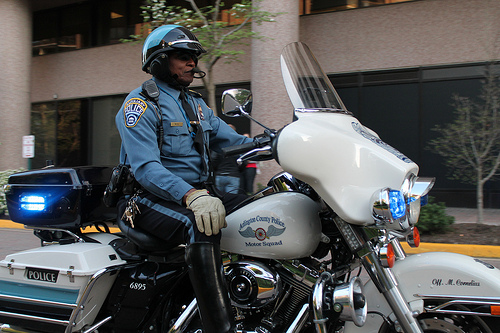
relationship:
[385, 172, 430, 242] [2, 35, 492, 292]
headlight of motorcycle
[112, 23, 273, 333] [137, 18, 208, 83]
cop wearing helmet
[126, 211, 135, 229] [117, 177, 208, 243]
key connected to pants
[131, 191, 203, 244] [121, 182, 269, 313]
blue stripe on side of pants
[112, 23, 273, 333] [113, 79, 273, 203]
cop wearing shirt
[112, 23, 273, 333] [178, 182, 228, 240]
cop wearing gloves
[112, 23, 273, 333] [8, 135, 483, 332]
cop riding a motorcycle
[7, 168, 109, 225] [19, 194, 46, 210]
case with light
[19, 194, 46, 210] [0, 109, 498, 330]
light on motorcycle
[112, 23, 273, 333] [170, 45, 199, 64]
cop wearing sunglasses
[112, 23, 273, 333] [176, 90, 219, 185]
cop wearing tie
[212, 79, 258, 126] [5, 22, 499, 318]
mirror on motorcycle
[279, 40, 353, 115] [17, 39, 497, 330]
wind shield on front motorcycle